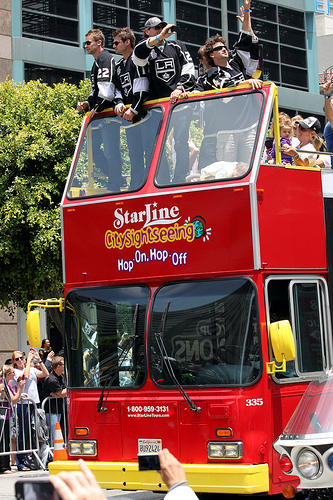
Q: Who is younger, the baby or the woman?
A: The baby is younger than the woman.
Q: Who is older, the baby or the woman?
A: The woman is older than the baby.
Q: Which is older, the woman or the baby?
A: The woman is older than the baby.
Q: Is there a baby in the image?
A: Yes, there is a baby.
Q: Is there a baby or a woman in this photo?
A: Yes, there is a baby.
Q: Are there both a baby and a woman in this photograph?
A: Yes, there are both a baby and a woman.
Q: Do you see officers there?
A: No, there are no officers.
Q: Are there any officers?
A: No, there are no officers.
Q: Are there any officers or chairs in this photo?
A: No, there are no officers or chairs.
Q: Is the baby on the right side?
A: Yes, the baby is on the right of the image.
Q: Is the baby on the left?
A: No, the baby is on the right of the image.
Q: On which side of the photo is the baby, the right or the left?
A: The baby is on the right of the image.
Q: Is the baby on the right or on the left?
A: The baby is on the right of the image.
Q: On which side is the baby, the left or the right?
A: The baby is on the right of the image.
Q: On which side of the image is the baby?
A: The baby is on the right of the image.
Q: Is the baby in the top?
A: Yes, the baby is in the top of the image.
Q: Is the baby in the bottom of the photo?
A: No, the baby is in the top of the image.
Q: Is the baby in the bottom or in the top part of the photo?
A: The baby is in the top of the image.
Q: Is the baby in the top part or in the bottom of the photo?
A: The baby is in the top of the image.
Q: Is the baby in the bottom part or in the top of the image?
A: The baby is in the top of the image.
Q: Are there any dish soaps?
A: No, there are no dish soaps.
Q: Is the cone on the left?
A: Yes, the cone is on the left of the image.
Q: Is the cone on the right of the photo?
A: No, the cone is on the left of the image.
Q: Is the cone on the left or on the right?
A: The cone is on the left of the image.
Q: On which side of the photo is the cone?
A: The cone is on the left of the image.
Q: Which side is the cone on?
A: The cone is on the left of the image.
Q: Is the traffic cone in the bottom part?
A: Yes, the traffic cone is in the bottom of the image.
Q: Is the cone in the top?
A: No, the cone is in the bottom of the image.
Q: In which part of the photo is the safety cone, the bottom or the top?
A: The safety cone is in the bottom of the image.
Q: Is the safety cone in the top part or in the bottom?
A: The safety cone is in the bottom of the image.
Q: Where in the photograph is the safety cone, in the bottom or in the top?
A: The safety cone is in the bottom of the image.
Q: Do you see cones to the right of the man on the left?
A: Yes, there is a cone to the right of the man.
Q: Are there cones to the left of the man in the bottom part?
A: No, the cone is to the right of the man.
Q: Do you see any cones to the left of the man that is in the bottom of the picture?
A: No, the cone is to the right of the man.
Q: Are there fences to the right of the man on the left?
A: No, there is a cone to the right of the man.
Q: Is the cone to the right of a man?
A: Yes, the cone is to the right of a man.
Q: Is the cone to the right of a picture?
A: No, the cone is to the right of a man.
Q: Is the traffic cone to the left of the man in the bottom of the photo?
A: No, the traffic cone is to the right of the man.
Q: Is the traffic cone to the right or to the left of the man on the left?
A: The traffic cone is to the right of the man.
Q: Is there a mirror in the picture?
A: Yes, there is a mirror.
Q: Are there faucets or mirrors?
A: Yes, there is a mirror.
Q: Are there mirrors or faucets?
A: Yes, there is a mirror.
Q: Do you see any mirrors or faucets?
A: Yes, there is a mirror.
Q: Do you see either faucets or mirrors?
A: Yes, there is a mirror.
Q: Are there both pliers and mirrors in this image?
A: No, there is a mirror but no pliers.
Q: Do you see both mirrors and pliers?
A: No, there is a mirror but no pliers.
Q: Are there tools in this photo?
A: No, there are no tools.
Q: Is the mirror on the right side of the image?
A: Yes, the mirror is on the right of the image.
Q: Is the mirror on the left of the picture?
A: No, the mirror is on the right of the image.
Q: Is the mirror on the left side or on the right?
A: The mirror is on the right of the image.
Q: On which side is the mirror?
A: The mirror is on the right of the image.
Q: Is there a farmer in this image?
A: No, there are no farmers.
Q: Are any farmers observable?
A: No, there are no farmers.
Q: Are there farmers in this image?
A: No, there are no farmers.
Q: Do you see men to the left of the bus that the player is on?
A: Yes, there is a man to the left of the bus.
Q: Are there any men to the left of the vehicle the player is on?
A: Yes, there is a man to the left of the bus.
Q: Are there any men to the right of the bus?
A: No, the man is to the left of the bus.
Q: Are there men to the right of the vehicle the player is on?
A: No, the man is to the left of the bus.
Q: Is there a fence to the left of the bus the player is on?
A: No, there is a man to the left of the bus.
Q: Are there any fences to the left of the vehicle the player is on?
A: No, there is a man to the left of the bus.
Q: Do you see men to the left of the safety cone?
A: Yes, there is a man to the left of the safety cone.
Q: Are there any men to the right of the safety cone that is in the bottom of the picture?
A: No, the man is to the left of the cone.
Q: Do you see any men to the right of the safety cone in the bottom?
A: No, the man is to the left of the cone.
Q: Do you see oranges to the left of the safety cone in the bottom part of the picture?
A: No, there is a man to the left of the safety cone.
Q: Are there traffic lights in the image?
A: No, there are no traffic lights.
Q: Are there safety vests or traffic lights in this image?
A: No, there are no traffic lights or safety vests.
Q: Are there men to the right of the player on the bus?
A: Yes, there is a man to the right of the player.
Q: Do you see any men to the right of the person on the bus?
A: Yes, there is a man to the right of the player.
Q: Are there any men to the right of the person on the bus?
A: Yes, there is a man to the right of the player.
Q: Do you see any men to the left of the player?
A: No, the man is to the right of the player.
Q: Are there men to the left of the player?
A: No, the man is to the right of the player.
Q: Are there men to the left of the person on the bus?
A: No, the man is to the right of the player.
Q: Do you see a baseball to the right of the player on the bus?
A: No, there is a man to the right of the player.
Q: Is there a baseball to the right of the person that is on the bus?
A: No, there is a man to the right of the player.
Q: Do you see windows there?
A: Yes, there is a window.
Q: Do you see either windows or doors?
A: Yes, there is a window.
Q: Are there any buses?
A: Yes, there is a bus.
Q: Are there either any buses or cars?
A: Yes, there is a bus.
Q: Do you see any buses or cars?
A: Yes, there is a bus.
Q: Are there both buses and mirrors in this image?
A: Yes, there are both a bus and a mirror.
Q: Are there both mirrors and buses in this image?
A: Yes, there are both a bus and a mirror.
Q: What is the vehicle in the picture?
A: The vehicle is a bus.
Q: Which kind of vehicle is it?
A: The vehicle is a bus.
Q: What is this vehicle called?
A: This is a bus.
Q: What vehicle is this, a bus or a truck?
A: This is a bus.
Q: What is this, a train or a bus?
A: This is a bus.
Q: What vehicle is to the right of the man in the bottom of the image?
A: The vehicle is a bus.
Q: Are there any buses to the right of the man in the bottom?
A: Yes, there is a bus to the right of the man.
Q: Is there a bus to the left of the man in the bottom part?
A: No, the bus is to the right of the man.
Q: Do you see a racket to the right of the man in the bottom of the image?
A: No, there is a bus to the right of the man.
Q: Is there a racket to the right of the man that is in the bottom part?
A: No, there is a bus to the right of the man.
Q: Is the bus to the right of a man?
A: Yes, the bus is to the right of a man.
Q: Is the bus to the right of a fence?
A: No, the bus is to the right of a man.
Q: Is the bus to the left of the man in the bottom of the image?
A: No, the bus is to the right of the man.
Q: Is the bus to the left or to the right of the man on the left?
A: The bus is to the right of the man.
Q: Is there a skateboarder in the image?
A: No, there are no skateboarders.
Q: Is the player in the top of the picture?
A: Yes, the player is in the top of the image.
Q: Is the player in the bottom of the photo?
A: No, the player is in the top of the image.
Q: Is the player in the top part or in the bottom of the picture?
A: The player is in the top of the image.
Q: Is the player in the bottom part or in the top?
A: The player is in the top of the image.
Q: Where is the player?
A: The player is on the bus.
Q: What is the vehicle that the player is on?
A: The vehicle is a bus.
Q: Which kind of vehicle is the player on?
A: The player is on the bus.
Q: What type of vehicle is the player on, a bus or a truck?
A: The player is on a bus.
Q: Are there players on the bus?
A: Yes, there is a player on the bus.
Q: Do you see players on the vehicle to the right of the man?
A: Yes, there is a player on the bus.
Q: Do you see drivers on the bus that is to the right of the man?
A: No, there is a player on the bus.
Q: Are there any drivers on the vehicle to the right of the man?
A: No, there is a player on the bus.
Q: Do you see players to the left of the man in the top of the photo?
A: Yes, there is a player to the left of the man.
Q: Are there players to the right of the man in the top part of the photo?
A: No, the player is to the left of the man.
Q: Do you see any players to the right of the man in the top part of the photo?
A: No, the player is to the left of the man.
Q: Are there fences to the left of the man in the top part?
A: No, there is a player to the left of the man.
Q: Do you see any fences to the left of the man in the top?
A: No, there is a player to the left of the man.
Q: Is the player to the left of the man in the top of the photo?
A: Yes, the player is to the left of the man.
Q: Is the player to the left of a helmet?
A: No, the player is to the left of the man.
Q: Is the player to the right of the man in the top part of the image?
A: No, the player is to the left of the man.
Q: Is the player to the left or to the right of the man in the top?
A: The player is to the left of the man.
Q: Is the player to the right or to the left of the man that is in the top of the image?
A: The player is to the left of the man.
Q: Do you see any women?
A: Yes, there is a woman.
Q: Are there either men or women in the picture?
A: Yes, there is a woman.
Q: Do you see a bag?
A: No, there are no bags.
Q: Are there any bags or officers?
A: No, there are no bags or officers.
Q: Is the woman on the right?
A: Yes, the woman is on the right of the image.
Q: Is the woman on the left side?
A: No, the woman is on the right of the image.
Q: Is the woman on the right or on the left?
A: The woman is on the right of the image.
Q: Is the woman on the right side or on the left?
A: The woman is on the right of the image.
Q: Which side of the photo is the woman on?
A: The woman is on the right of the image.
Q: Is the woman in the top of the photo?
A: Yes, the woman is in the top of the image.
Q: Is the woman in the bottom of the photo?
A: No, the woman is in the top of the image.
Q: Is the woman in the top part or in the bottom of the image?
A: The woman is in the top of the image.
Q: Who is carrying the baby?
A: The woman is carrying the baby.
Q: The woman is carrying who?
A: The woman is carrying a baby.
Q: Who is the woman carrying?
A: The woman is carrying a baby.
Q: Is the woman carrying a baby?
A: Yes, the woman is carrying a baby.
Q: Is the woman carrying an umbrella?
A: No, the woman is carrying a baby.